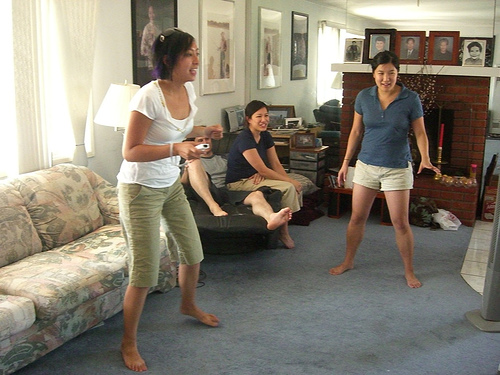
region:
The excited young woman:
[116, 29, 222, 371]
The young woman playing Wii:
[121, 28, 210, 370]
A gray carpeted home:
[0, 201, 499, 373]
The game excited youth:
[117, 28, 444, 370]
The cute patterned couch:
[1, 163, 188, 373]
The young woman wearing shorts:
[329, 48, 441, 285]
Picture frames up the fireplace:
[362, 25, 498, 73]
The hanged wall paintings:
[195, 0, 309, 95]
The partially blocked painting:
[130, 0, 178, 84]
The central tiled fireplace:
[336, 74, 484, 228]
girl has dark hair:
[126, 28, 195, 68]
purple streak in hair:
[145, 62, 178, 90]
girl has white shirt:
[147, 87, 200, 199]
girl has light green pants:
[100, 190, 207, 292]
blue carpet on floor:
[230, 285, 302, 373]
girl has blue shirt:
[369, 53, 415, 173]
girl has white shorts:
[336, 163, 416, 193]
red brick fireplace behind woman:
[337, 70, 472, 223]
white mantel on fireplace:
[308, 49, 482, 99]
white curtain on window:
[31, 28, 121, 157]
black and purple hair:
[140, 16, 210, 64]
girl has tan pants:
[113, 183, 200, 287]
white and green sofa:
[0, 168, 126, 300]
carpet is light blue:
[285, 291, 383, 369]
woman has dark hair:
[367, 45, 426, 78]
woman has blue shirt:
[352, 79, 424, 168]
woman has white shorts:
[341, 146, 432, 201]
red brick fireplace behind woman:
[312, 35, 489, 227]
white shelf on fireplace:
[320, 43, 495, 85]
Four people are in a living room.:
[111, 26, 443, 372]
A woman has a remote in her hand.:
[110, 22, 215, 167]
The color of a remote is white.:
[182, 131, 212, 152]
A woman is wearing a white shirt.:
[115, 76, 197, 186]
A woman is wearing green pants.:
[110, 175, 205, 290]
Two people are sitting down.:
[182, 98, 312, 257]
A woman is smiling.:
[235, 94, 275, 132]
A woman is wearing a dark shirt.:
[220, 125, 278, 188]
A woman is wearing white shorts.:
[347, 151, 417, 196]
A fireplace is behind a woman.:
[325, 59, 494, 234]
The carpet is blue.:
[270, 293, 319, 358]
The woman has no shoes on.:
[118, 295, 255, 374]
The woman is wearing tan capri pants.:
[110, 179, 268, 288]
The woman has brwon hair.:
[150, 28, 207, 83]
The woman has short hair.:
[147, 24, 209, 90]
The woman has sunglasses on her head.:
[144, 24, 214, 87]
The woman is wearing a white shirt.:
[120, 80, 199, 186]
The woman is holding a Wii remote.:
[171, 136, 218, 161]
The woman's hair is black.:
[367, 48, 404, 95]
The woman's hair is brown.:
[241, 97, 271, 132]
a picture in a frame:
[200, 2, 240, 98]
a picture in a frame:
[128, 2, 177, 86]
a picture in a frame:
[258, 7, 285, 88]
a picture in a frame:
[288, 12, 308, 82]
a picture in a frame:
[363, 24, 392, 61]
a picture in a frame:
[396, 28, 422, 63]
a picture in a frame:
[461, 35, 491, 67]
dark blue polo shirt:
[353, 86, 420, 170]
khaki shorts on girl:
[353, 157, 420, 191]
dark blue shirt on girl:
[227, 130, 277, 182]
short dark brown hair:
[148, 27, 193, 82]